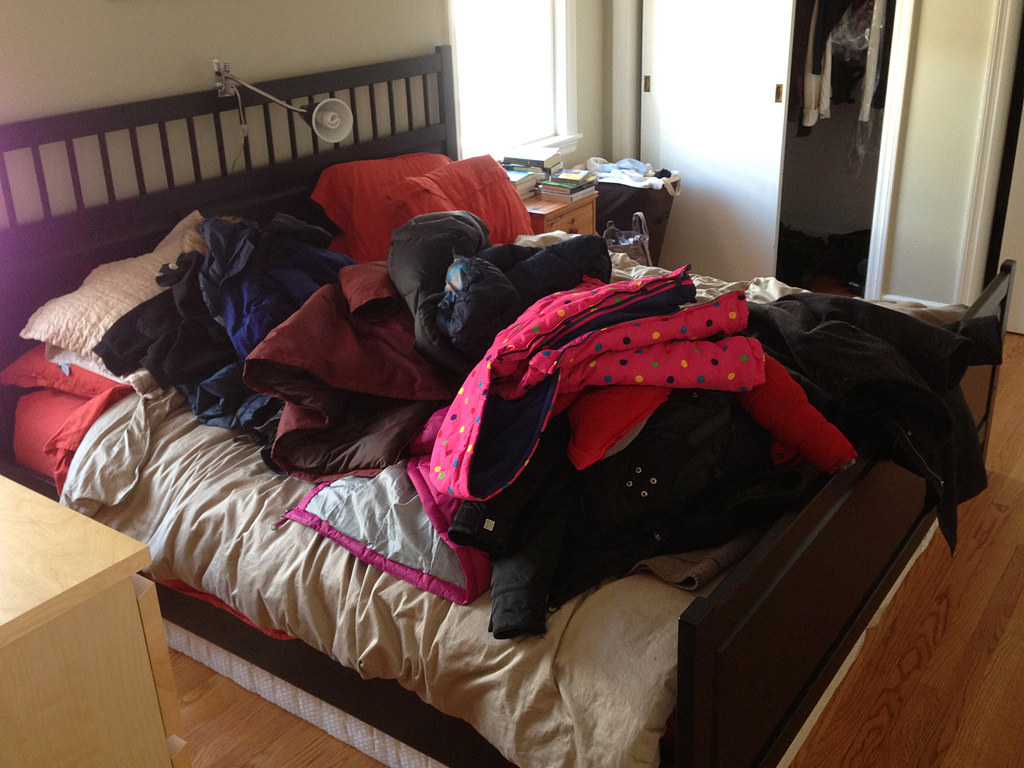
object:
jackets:
[88, 203, 1003, 637]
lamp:
[202, 47, 353, 147]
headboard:
[5, 35, 456, 298]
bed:
[0, 46, 1008, 767]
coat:
[432, 267, 779, 506]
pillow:
[310, 148, 538, 269]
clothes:
[789, 0, 913, 178]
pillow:
[0, 345, 137, 403]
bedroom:
[0, 0, 1024, 764]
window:
[446, 5, 570, 169]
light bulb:
[320, 105, 344, 133]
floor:
[165, 272, 1024, 766]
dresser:
[0, 481, 148, 766]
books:
[539, 167, 597, 202]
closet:
[607, 1, 1024, 316]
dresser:
[520, 167, 600, 236]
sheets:
[9, 388, 122, 475]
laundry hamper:
[558, 158, 679, 271]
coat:
[202, 206, 360, 358]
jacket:
[236, 258, 461, 477]